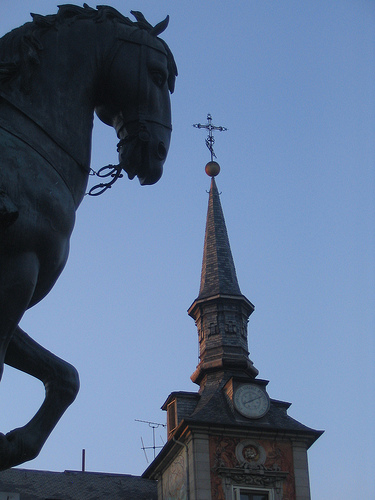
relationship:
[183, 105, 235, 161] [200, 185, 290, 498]
cross on building